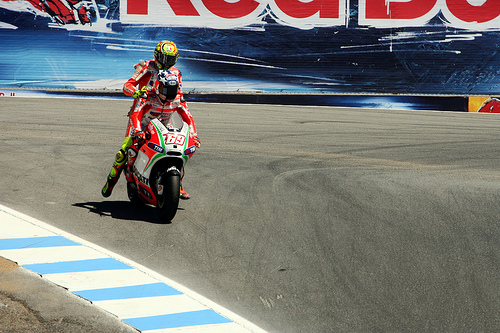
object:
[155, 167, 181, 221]
tire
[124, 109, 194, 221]
motorcycle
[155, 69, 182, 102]
helmet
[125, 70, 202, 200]
people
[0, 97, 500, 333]
race track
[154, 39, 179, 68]
helmet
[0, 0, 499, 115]
advertisement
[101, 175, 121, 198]
boot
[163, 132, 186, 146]
number 69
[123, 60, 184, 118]
suit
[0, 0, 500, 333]
picture